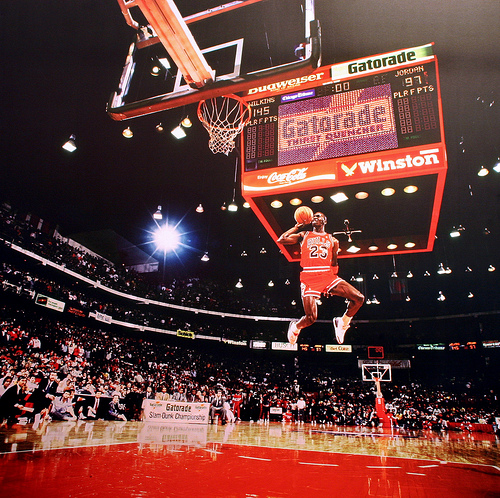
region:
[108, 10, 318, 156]
a basketball net and backboard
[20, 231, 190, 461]
crowd watching a basketball game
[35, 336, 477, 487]
basketball court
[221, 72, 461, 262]
Jumbo tron at sporting event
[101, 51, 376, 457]
basketball player making a slam dunk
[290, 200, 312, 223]
a basketball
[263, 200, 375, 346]
basketball player jumping in the air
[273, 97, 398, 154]
electric gatorade advertisement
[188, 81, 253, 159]
a basketball net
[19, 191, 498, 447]
event center seating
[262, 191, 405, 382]
man shooting basketball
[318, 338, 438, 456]
basket ball goal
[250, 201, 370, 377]
man holding a basketball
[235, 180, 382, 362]
man wearing basketball jersey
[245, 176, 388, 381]
man wearing basket ball shorts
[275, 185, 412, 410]
man wearing pair of tennis shoes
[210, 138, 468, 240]
the letter w on a advertisement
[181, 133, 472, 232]
the letter i on a advertisement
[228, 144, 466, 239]
the letter n on a advertisement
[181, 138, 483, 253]
the letter s on a advertisement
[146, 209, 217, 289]
reflection from stadium light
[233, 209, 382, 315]
basketball player shooting the ball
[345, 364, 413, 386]
basketball hoop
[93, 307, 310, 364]
advertisements in the arena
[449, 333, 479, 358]
scoreboard on the advertiement wall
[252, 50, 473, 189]
scoreboard in center of arena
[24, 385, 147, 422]
people sitting on the basketball court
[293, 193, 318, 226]
basketball is orange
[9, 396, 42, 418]
man holding papers in hand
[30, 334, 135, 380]
fans in the arena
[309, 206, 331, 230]
the head of a man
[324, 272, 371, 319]
the leg of a man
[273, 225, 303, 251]
the arm of a man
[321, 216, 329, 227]
the ear of a man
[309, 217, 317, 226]
the mouth of a man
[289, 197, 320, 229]
an orange basketball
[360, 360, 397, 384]
a clear backboard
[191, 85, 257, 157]
a basketball hoop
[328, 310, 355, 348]
a white basketball shoe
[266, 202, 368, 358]
a man in the air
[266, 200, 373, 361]
Basketball player in the air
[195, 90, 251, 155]
Basketball hoop and net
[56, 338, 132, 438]
Crowd at a basketball game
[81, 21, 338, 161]
Hoop and backboard for basketball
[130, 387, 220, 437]
Advertising at a basketball game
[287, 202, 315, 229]
Basketball in someone's hand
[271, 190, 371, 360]
Basketball player shooting a basket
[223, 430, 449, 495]
Markings on a basketball court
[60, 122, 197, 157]
Lighting in a basketball court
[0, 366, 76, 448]
Coaches at a basketball game